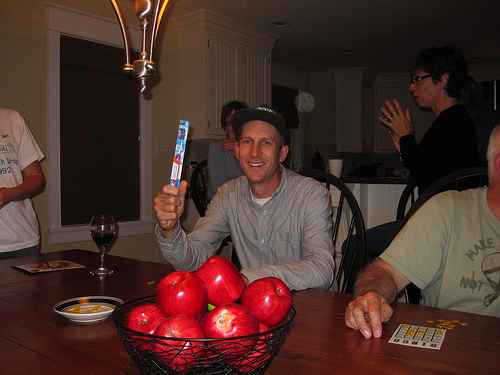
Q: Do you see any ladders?
A: No, there are no ladders.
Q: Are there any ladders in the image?
A: No, there are no ladders.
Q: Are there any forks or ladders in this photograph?
A: No, there are no ladders or forks.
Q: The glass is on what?
A: The glass is on the table.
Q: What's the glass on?
A: The glass is on the table.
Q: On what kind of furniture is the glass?
A: The glass is on the table.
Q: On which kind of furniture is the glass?
A: The glass is on the table.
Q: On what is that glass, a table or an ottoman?
A: The glass is on a table.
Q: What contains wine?
A: The glass contains wine.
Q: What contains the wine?
A: The glass contains wine.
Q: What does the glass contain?
A: The glass contains wine.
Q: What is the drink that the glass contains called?
A: The drink is wine.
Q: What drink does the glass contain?
A: The glass contains wine.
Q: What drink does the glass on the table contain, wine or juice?
A: The glass contains wine.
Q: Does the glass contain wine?
A: Yes, the glass contains wine.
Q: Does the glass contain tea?
A: No, the glass contains wine.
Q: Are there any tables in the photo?
A: Yes, there is a table.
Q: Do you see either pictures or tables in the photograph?
A: Yes, there is a table.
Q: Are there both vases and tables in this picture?
A: No, there is a table but no vases.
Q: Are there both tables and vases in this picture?
A: No, there is a table but no vases.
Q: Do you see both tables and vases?
A: No, there is a table but no vases.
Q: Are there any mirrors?
A: No, there are no mirrors.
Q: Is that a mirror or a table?
A: That is a table.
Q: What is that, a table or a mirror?
A: That is a table.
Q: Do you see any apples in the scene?
A: Yes, there is an apple.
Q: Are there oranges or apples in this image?
A: Yes, there is an apple.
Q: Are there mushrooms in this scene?
A: No, there are no mushrooms.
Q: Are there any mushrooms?
A: No, there are no mushrooms.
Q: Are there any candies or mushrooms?
A: No, there are no mushrooms or candies.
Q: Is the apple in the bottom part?
A: Yes, the apple is in the bottom of the image.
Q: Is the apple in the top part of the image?
A: No, the apple is in the bottom of the image.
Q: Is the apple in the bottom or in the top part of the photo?
A: The apple is in the bottom of the image.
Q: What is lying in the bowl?
A: The apple is lying in the bowl.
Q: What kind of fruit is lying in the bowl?
A: The fruit is an apple.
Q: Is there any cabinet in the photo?
A: Yes, there is a cabinet.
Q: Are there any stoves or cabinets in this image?
A: Yes, there is a cabinet.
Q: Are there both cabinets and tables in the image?
A: Yes, there are both a cabinet and a table.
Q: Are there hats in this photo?
A: Yes, there is a hat.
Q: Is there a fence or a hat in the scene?
A: Yes, there is a hat.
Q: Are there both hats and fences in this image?
A: No, there is a hat but no fences.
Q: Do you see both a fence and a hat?
A: No, there is a hat but no fences.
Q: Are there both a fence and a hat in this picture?
A: No, there is a hat but no fences.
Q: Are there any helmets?
A: No, there are no helmets.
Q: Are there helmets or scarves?
A: No, there are no helmets or scarves.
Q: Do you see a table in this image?
A: Yes, there is a table.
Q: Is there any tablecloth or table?
A: Yes, there is a table.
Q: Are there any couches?
A: No, there are no couches.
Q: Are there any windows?
A: Yes, there is a window.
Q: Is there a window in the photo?
A: Yes, there is a window.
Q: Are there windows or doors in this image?
A: Yes, there is a window.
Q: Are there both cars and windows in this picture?
A: No, there is a window but no cars.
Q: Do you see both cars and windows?
A: No, there is a window but no cars.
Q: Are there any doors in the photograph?
A: No, there are no doors.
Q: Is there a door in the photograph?
A: No, there are no doors.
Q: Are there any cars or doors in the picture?
A: No, there are no doors or cars.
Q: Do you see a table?
A: Yes, there is a table.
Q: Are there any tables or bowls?
A: Yes, there is a table.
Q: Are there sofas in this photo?
A: No, there are no sofas.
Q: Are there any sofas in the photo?
A: No, there are no sofas.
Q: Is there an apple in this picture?
A: Yes, there is an apple.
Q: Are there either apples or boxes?
A: Yes, there is an apple.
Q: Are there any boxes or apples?
A: Yes, there is an apple.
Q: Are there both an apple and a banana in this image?
A: No, there is an apple but no bananas.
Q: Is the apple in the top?
A: No, the apple is in the bottom of the image.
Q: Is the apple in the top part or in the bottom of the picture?
A: The apple is in the bottom of the image.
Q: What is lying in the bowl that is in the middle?
A: The apple is lying in the bowl.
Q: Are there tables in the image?
A: Yes, there is a table.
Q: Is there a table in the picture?
A: Yes, there is a table.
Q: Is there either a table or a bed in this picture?
A: Yes, there is a table.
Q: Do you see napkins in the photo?
A: No, there are no napkins.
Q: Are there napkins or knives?
A: No, there are no napkins or knives.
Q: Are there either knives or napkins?
A: No, there are no napkins or knives.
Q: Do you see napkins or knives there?
A: No, there are no napkins or knives.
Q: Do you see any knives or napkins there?
A: No, there are no napkins or knives.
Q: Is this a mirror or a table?
A: This is a table.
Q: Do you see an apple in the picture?
A: Yes, there is an apple.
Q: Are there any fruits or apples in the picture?
A: Yes, there is an apple.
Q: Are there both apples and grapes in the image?
A: No, there is an apple but no grapes.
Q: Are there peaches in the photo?
A: No, there are no peaches.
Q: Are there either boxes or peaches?
A: No, there are no peaches or boxes.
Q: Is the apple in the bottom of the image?
A: Yes, the apple is in the bottom of the image.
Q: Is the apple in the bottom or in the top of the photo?
A: The apple is in the bottom of the image.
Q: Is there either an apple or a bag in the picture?
A: Yes, there is an apple.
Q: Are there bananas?
A: No, there are no bananas.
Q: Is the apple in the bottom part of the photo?
A: Yes, the apple is in the bottom of the image.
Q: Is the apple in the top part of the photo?
A: No, the apple is in the bottom of the image.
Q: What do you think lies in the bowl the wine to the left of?
A: The apple lies in the bowl.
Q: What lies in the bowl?
A: The apple lies in the bowl.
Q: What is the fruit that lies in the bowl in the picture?
A: The fruit is an apple.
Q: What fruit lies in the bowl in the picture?
A: The fruit is an apple.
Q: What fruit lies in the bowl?
A: The fruit is an apple.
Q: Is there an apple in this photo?
A: Yes, there is an apple.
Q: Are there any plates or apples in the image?
A: Yes, there is an apple.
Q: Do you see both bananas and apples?
A: No, there is an apple but no bananas.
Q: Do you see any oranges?
A: No, there are no oranges.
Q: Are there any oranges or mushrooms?
A: No, there are no oranges or mushrooms.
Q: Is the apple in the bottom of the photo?
A: Yes, the apple is in the bottom of the image.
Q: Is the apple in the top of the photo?
A: No, the apple is in the bottom of the image.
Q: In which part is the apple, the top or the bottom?
A: The apple is in the bottom of the image.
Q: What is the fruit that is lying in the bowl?
A: The fruit is an apple.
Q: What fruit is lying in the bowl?
A: The fruit is an apple.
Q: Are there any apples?
A: Yes, there are apples.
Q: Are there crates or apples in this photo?
A: Yes, there are apples.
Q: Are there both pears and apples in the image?
A: No, there are apples but no pears.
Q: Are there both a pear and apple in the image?
A: No, there are apples but no pears.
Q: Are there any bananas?
A: No, there are no bananas.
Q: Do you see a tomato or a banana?
A: No, there are no bananas or tomatoes.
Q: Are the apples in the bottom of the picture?
A: Yes, the apples are in the bottom of the image.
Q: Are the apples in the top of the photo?
A: No, the apples are in the bottom of the image.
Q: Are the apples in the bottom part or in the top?
A: The apples are in the bottom of the image.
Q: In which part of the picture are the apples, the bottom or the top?
A: The apples are in the bottom of the image.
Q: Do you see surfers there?
A: No, there are no surfers.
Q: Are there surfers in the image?
A: No, there are no surfers.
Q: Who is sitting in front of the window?
A: The man is sitting in front of the window.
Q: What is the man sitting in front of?
A: The man is sitting in front of the window.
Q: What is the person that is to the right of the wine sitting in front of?
A: The man is sitting in front of the window.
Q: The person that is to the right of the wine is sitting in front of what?
A: The man is sitting in front of the window.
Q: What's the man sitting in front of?
A: The man is sitting in front of the window.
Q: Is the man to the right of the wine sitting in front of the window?
A: Yes, the man is sitting in front of the window.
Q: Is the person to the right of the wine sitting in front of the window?
A: Yes, the man is sitting in front of the window.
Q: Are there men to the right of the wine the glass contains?
A: Yes, there is a man to the right of the wine.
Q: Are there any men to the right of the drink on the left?
A: Yes, there is a man to the right of the wine.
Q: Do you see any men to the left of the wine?
A: No, the man is to the right of the wine.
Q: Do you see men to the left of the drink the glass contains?
A: No, the man is to the right of the wine.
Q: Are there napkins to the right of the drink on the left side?
A: No, there is a man to the right of the wine.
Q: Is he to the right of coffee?
A: No, the man is to the right of the wine.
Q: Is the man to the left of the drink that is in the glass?
A: No, the man is to the right of the wine.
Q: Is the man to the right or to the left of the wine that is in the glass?
A: The man is to the right of the wine.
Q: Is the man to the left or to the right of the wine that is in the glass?
A: The man is to the right of the wine.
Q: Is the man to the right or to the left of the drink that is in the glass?
A: The man is to the right of the wine.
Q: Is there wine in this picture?
A: Yes, there is wine.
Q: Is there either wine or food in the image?
A: Yes, there is wine.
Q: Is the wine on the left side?
A: Yes, the wine is on the left of the image.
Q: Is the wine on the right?
A: No, the wine is on the left of the image.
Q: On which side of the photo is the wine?
A: The wine is on the left of the image.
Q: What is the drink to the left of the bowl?
A: The drink is wine.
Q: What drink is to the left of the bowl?
A: The drink is wine.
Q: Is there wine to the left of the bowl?
A: Yes, there is wine to the left of the bowl.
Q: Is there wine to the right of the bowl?
A: No, the wine is to the left of the bowl.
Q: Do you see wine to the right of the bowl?
A: No, the wine is to the left of the bowl.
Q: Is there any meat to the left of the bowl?
A: No, there is wine to the left of the bowl.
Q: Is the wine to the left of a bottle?
A: No, the wine is to the left of a bowl.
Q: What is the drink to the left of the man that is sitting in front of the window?
A: The drink is wine.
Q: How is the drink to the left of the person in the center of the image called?
A: The drink is wine.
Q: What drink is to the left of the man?
A: The drink is wine.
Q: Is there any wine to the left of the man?
A: Yes, there is wine to the left of the man.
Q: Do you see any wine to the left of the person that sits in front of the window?
A: Yes, there is wine to the left of the man.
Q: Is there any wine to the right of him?
A: No, the wine is to the left of the man.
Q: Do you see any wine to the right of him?
A: No, the wine is to the left of the man.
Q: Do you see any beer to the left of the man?
A: No, there is wine to the left of the man.